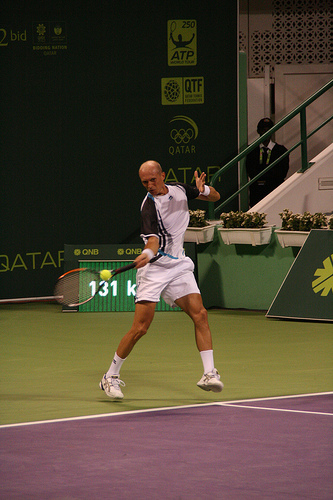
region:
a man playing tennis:
[47, 135, 237, 408]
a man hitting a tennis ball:
[40, 149, 221, 402]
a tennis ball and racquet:
[53, 258, 136, 317]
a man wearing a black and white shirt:
[128, 155, 210, 261]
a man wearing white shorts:
[115, 248, 209, 297]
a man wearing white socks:
[99, 348, 229, 382]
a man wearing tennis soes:
[93, 368, 227, 403]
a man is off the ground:
[83, 378, 244, 406]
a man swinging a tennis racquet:
[32, 234, 170, 321]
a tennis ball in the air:
[91, 266, 116, 285]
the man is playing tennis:
[53, 157, 228, 395]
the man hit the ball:
[55, 160, 228, 390]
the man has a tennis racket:
[54, 156, 223, 400]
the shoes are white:
[97, 370, 222, 393]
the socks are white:
[110, 354, 216, 374]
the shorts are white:
[137, 266, 201, 299]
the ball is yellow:
[96, 270, 115, 280]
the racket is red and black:
[44, 254, 163, 305]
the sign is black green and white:
[64, 245, 198, 311]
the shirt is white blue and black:
[133, 181, 202, 266]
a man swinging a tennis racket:
[34, 151, 279, 420]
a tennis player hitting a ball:
[33, 148, 262, 412]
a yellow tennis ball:
[96, 266, 114, 283]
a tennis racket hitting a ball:
[49, 259, 137, 308]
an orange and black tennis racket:
[47, 262, 135, 310]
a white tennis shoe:
[193, 369, 225, 393]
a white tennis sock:
[191, 346, 222, 369]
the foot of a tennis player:
[198, 370, 224, 392]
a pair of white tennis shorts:
[128, 253, 201, 304]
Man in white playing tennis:
[97, 157, 226, 402]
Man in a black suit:
[239, 115, 291, 207]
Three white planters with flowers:
[181, 206, 329, 250]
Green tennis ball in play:
[93, 265, 114, 284]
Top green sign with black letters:
[163, 13, 197, 66]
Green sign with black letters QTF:
[180, 73, 207, 108]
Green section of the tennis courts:
[2, 298, 332, 426]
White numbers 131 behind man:
[86, 276, 119, 300]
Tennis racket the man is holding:
[50, 249, 165, 309]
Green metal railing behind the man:
[205, 68, 329, 223]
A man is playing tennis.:
[42, 164, 228, 408]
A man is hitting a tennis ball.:
[53, 166, 220, 390]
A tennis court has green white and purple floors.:
[8, 318, 88, 498]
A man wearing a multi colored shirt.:
[133, 163, 190, 266]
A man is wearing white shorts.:
[138, 275, 216, 314]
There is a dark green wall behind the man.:
[3, 90, 130, 161]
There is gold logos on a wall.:
[164, 51, 212, 173]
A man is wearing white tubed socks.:
[195, 348, 233, 370]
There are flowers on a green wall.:
[216, 213, 272, 253]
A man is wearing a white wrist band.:
[100, 162, 227, 205]